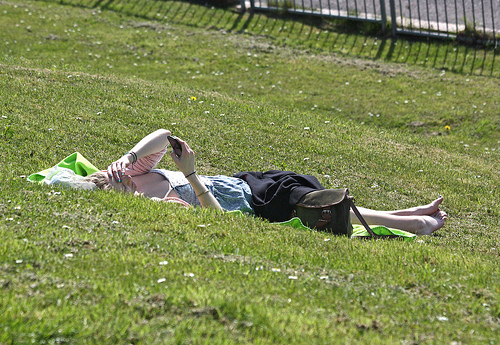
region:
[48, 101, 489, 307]
Woman laying in the grass.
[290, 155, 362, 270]
Bag by the woman.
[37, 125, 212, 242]
Towel under the woman.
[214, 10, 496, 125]
Fence against the grass.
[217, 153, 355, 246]
Jacket on the woman.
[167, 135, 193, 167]
Cell phone in the woman's hands.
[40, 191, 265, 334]
White flowers in the grass.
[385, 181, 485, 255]
Bare feet on the woman.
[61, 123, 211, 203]
Woman with bracelet.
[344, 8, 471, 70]
Sky behind the fence.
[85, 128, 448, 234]
a girl laying in the grass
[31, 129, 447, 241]
a girl laying on a blanket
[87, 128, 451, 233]
a girl reading her phone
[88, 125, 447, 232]
a girl shading her eyes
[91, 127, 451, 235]
a barefoot girl on the grass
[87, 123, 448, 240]
a barefoot girl on a blanket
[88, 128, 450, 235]
a barefoot girl shading her eyes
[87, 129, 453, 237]
a young woman laying down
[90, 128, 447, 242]
a young woman on her back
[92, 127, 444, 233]
a young woman with blond hair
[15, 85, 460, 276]
woman laying down on grass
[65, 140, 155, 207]
shielding eyes with hand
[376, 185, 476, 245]
bare feet touching each other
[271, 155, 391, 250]
brown handbag near legs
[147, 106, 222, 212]
hand holding dark cellphone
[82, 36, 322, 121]
white flowers growing with grass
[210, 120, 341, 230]
dark jacket placed over hips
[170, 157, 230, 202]
two bracelets on arm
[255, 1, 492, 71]
railing in front of water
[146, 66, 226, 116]
one yellow flower in grass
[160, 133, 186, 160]
A black cell phone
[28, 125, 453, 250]
A woman laying on a green blanket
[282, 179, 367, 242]
A brown purse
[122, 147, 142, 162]
A set of bracelets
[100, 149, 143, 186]
A hand with blue fingernail polish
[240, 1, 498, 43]
A black fence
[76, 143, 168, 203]
A hand touching a woman's head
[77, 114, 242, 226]
A woman looking at her phone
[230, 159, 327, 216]
A black blanket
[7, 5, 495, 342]
A green grassy area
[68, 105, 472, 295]
A woman is laying on the grass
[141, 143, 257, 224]
Woman is wearing a light colored tank top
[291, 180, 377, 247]
Woman has a purse by her leg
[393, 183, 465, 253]
Woman is not wearing any shoes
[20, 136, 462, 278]
Woman has a neon green towel under her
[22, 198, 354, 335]
White flowers are in the grass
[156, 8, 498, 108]
Fence is casting a shadow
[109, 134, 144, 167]
Woman is wearing a dark colored wristband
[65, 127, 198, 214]
Woman is looking at her phone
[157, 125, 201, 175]
Woman's phone is black in color